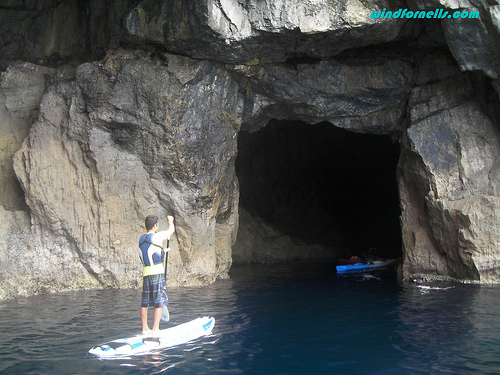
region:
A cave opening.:
[213, 97, 433, 290]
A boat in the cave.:
[316, 237, 418, 293]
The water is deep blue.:
[276, 303, 416, 368]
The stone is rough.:
[78, 50, 218, 195]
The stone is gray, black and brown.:
[83, 64, 217, 196]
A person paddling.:
[83, 193, 248, 367]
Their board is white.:
[61, 293, 226, 373]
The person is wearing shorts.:
[124, 267, 185, 322]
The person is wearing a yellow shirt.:
[117, 207, 187, 283]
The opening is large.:
[211, 95, 426, 294]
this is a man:
[141, 219, 183, 321]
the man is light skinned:
[158, 232, 172, 238]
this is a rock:
[396, 114, 471, 258]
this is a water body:
[265, 300, 365, 367]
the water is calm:
[288, 308, 325, 344]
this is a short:
[150, 281, 157, 297]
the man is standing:
[132, 215, 177, 325]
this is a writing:
[366, 5, 476, 17]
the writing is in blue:
[371, 5, 476, 20]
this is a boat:
[323, 260, 389, 267]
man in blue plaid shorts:
[143, 270, 172, 311]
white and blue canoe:
[85, 312, 235, 362]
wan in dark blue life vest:
[136, 213, 178, 280]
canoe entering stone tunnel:
[331, 234, 403, 280]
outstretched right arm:
[126, 197, 183, 342]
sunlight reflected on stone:
[1, 123, 236, 300]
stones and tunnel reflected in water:
[0, 275, 497, 372]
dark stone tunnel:
[223, 109, 408, 280]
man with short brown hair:
[137, 205, 180, 345]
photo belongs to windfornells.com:
[361, 0, 482, 23]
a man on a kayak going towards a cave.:
[86, 207, 237, 364]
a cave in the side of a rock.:
[217, 107, 412, 298]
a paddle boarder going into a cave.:
[326, 243, 402, 283]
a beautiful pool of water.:
[1, 282, 491, 373]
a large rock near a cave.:
[389, 94, 497, 289]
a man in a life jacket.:
[133, 202, 186, 267]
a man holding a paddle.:
[159, 219, 190, 293]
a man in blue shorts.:
[132, 264, 175, 312]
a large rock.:
[11, 87, 186, 285]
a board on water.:
[96, 308, 237, 368]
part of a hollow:
[294, 175, 331, 222]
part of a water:
[291, 292, 350, 338]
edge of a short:
[143, 295, 163, 310]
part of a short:
[148, 287, 168, 319]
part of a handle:
[161, 248, 173, 279]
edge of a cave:
[186, 208, 220, 263]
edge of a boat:
[183, 319, 208, 342]